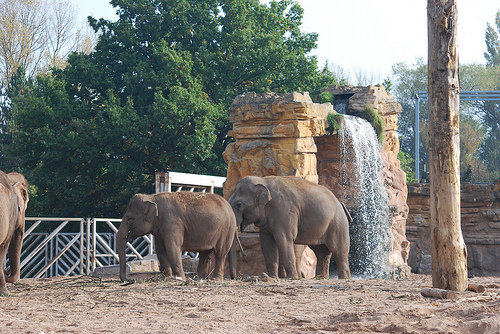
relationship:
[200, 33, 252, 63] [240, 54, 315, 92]
part of branch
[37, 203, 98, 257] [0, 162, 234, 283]
part of fence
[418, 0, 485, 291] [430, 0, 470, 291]
part of part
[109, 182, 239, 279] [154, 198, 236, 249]
elephant has body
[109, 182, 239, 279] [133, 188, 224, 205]
elephant has back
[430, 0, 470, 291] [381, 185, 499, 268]
part of wall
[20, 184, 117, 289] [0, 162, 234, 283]
edge of fence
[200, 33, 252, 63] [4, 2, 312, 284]
part of tree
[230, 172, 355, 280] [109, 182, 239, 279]
elephant behind elephant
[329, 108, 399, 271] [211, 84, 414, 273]
water coming out of structure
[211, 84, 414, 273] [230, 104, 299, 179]
structure made of rock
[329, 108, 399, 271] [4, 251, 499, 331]
water hitting ground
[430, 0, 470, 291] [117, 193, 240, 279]
part near elephant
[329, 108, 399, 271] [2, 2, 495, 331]
water fall in enclosure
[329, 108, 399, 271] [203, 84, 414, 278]
water spilling from structure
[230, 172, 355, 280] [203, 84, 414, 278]
elephant next to structure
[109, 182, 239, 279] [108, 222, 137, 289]
elephant has trunk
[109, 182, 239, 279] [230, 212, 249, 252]
elephant has tail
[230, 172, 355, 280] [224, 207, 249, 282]
elephant has trunk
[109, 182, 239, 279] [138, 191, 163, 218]
elephant has ear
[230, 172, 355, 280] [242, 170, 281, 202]
elephant has ear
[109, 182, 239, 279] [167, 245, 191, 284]
elephant has leg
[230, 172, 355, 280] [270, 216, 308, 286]
elephant has leg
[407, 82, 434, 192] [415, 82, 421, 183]
part of part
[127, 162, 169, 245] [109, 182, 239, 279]
part of elephant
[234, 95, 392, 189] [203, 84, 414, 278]
part of structure